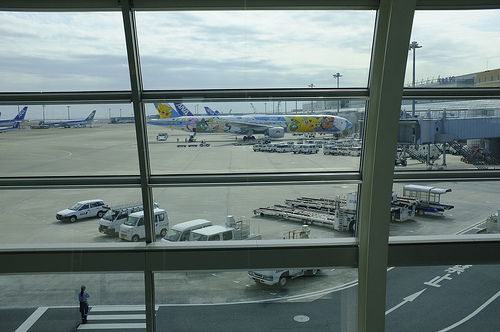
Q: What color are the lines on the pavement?
A: White.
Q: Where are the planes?
A: On the tarmac.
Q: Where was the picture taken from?
A: From the inside.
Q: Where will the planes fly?
A: In the sky.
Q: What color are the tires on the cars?
A: Black.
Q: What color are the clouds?
A: White.